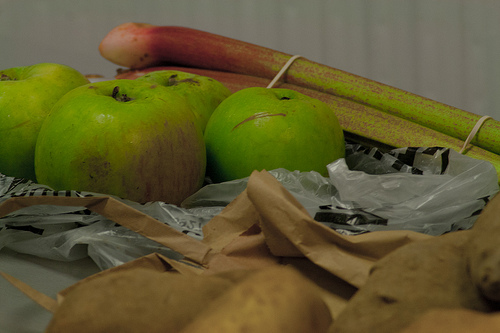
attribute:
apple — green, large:
[202, 88, 349, 177]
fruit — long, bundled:
[97, 23, 500, 152]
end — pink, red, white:
[99, 22, 158, 70]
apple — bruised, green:
[32, 81, 208, 207]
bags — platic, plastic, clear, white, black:
[1, 146, 499, 258]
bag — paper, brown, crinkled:
[1, 170, 436, 318]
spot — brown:
[74, 153, 116, 184]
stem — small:
[110, 83, 123, 102]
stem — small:
[281, 95, 291, 101]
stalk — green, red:
[244, 47, 500, 149]